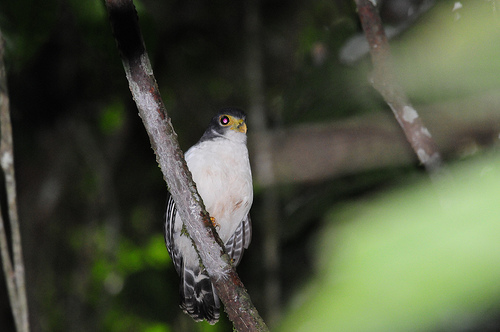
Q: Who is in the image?
A: Bird.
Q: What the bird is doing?
A: Staring.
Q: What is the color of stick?
A: Black.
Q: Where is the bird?
A: On the stem.